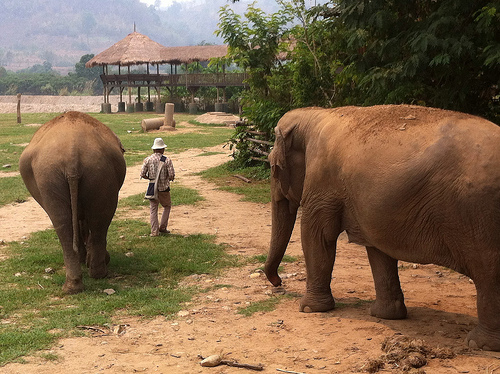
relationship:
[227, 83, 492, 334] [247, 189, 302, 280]
elephant has trunk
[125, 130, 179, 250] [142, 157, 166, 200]
man with bag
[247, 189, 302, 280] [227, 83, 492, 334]
trunk of elephant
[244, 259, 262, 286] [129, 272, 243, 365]
rock on ground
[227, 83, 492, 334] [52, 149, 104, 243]
elephant has tail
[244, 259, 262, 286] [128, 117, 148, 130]
rock in grass